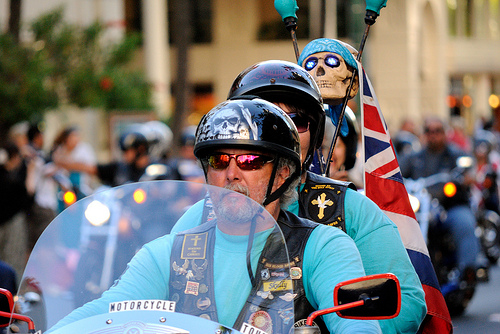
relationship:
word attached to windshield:
[108, 298, 177, 313] [5, 180, 294, 333]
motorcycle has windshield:
[0, 180, 400, 332] [5, 180, 294, 333]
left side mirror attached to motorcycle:
[308, 272, 402, 321] [0, 180, 400, 332]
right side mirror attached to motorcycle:
[0, 287, 35, 333] [0, 180, 400, 332]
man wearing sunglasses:
[43, 97, 381, 333] [202, 151, 276, 171]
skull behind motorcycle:
[298, 39, 362, 102] [0, 180, 400, 332]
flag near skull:
[353, 55, 454, 333] [298, 39, 362, 102]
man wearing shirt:
[43, 97, 381, 333] [40, 224, 380, 333]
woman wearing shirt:
[171, 60, 428, 333] [172, 174, 428, 333]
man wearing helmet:
[43, 97, 381, 333] [192, 99, 303, 224]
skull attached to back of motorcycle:
[298, 39, 362, 102] [0, 180, 400, 332]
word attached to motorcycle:
[108, 298, 177, 313] [0, 180, 400, 332]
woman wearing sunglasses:
[171, 60, 428, 333] [284, 109, 316, 134]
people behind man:
[3, 122, 116, 289] [43, 97, 381, 333]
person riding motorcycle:
[399, 120, 490, 285] [394, 155, 479, 316]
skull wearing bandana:
[298, 39, 362, 102] [298, 37, 358, 70]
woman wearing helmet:
[171, 60, 428, 333] [227, 60, 326, 150]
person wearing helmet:
[321, 104, 366, 193] [325, 105, 360, 169]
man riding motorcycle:
[43, 97, 381, 333] [0, 180, 400, 332]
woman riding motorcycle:
[171, 60, 428, 333] [0, 180, 400, 332]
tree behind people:
[0, 7, 155, 133] [3, 122, 116, 289]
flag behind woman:
[353, 55, 454, 333] [171, 60, 428, 333]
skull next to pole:
[298, 39, 362, 102] [327, 0, 385, 176]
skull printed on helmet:
[210, 109, 241, 140] [192, 99, 303, 224]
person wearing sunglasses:
[399, 120, 490, 285] [424, 128, 442, 136]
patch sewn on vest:
[180, 231, 209, 260] [167, 208, 331, 332]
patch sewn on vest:
[183, 280, 199, 297] [167, 208, 331, 332]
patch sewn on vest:
[249, 310, 272, 333] [167, 208, 331, 332]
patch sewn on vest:
[259, 255, 300, 272] [167, 208, 331, 332]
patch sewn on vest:
[306, 189, 335, 221] [298, 171, 358, 234]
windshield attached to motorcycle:
[5, 180, 294, 333] [0, 180, 400, 332]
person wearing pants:
[399, 120, 490, 285] [444, 206, 478, 272]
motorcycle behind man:
[43, 165, 178, 308] [43, 97, 381, 333]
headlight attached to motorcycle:
[406, 193, 420, 213] [394, 155, 479, 316]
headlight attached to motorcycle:
[83, 200, 109, 226] [43, 165, 178, 308]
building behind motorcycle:
[125, 2, 500, 120] [0, 180, 400, 332]